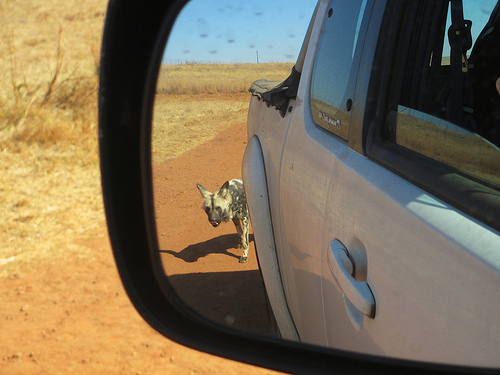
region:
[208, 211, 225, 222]
Dog's nose is black.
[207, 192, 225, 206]
Dog's head is mostly yellowish brown.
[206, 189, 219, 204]
Small black line on dog's head.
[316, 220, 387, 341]
Car door knob.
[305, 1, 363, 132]
Small window on car door.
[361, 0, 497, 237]
Big window on car door.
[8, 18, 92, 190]
Yellow weeds and bushes.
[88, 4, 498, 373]
Rear view mirror on car.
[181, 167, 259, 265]
Black and yellowish brown dog.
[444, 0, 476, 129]
Black seatbelt in car.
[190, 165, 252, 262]
hyena on side of road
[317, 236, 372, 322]
silver car door handle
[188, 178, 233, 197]
pointed ears of hyena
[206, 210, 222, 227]
black nose of hyena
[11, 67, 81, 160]
dead plant on side of road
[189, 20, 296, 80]
water mark on side mirror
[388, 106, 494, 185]
partially open side window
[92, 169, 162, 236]
black trim of mirror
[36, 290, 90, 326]
red clay dirt road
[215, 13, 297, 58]
blue sky in mirror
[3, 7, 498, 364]
Outdoor scene, bright, sunlit day.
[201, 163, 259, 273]
Wild, spotted canine.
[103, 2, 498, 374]
Close-up car mirror.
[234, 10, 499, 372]
Side view of car and door with handle, seen in mirror.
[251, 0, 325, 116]
Back of vehicle with black, plastic cover.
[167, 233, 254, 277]
Shadow of dog.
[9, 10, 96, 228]
Rock by road.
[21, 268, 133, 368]
Brown, dirt road.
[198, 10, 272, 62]
Flawless, blue sky.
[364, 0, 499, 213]
Car window, two-thirds open.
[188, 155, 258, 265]
a dog reflecting in mirror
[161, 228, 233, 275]
shadow on dog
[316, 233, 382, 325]
handle of car on door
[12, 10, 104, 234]
dry grass is yellow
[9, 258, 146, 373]
road is not paved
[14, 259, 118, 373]
road is color orange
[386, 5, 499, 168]
window of car is open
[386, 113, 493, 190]
part of a window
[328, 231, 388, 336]
part dented underneath the handle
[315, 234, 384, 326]
handle is white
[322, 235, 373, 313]
a silver door handle on a door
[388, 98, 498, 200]
a rolled down glass window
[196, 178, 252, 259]
a black and tan hyeana licking his lips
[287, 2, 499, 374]
a silver door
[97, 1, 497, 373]
a rear view mirror mounted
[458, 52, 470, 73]
the silver buckle of a seat belt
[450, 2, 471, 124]
a black seat belt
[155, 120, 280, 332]
a deep brown dirt trail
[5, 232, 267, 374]
a deep tan dirt trail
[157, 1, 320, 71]
a bright blue sky